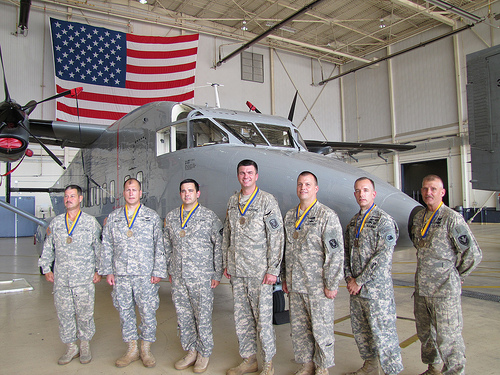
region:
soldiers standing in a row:
[20, 147, 490, 357]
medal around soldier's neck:
[58, 206, 83, 246]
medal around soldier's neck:
[116, 196, 150, 243]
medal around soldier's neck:
[168, 181, 206, 246]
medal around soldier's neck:
[231, 164, 256, 231]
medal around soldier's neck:
[288, 176, 320, 243]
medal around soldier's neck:
[341, 171, 376, 243]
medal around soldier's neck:
[411, 180, 448, 252]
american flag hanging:
[36, 17, 203, 114]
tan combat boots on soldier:
[43, 335, 93, 367]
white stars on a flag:
[51, 21, 119, 81]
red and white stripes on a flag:
[133, 35, 186, 107]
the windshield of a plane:
[143, 114, 303, 153]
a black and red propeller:
[0, 76, 63, 172]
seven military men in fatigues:
[47, 161, 498, 364]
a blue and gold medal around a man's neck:
[235, 196, 257, 223]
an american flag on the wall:
[41, 15, 198, 117]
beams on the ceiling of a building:
[227, 1, 488, 71]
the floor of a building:
[7, 275, 47, 345]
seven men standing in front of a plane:
[37, 77, 439, 277]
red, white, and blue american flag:
[43, 8, 218, 139]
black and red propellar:
[0, 45, 93, 203]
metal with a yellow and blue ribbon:
[61, 210, 86, 246]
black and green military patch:
[453, 228, 474, 251]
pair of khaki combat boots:
[110, 335, 165, 370]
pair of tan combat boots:
[50, 334, 98, 366]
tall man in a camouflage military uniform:
[218, 157, 285, 373]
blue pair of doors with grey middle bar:
[0, 193, 37, 243]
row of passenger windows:
[80, 177, 120, 208]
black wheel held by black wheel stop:
[270, 277, 295, 327]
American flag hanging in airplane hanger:
[35, 6, 217, 140]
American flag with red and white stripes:
[39, 6, 222, 133]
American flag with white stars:
[34, 8, 226, 127]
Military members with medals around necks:
[22, 165, 486, 366]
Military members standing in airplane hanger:
[27, 147, 476, 359]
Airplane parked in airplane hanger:
[34, 68, 466, 300]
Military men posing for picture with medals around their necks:
[23, 131, 483, 352]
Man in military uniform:
[25, 164, 116, 366]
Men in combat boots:
[25, 158, 170, 374]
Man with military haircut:
[392, 154, 486, 374]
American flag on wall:
[18, 30, 200, 127]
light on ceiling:
[236, 14, 257, 36]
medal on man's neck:
[57, 210, 85, 252]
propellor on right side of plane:
[0, 78, 84, 184]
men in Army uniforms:
[34, 157, 484, 374]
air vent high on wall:
[233, 50, 265, 84]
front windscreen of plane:
[165, 121, 279, 161]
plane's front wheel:
[275, 287, 288, 331]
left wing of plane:
[308, 134, 428, 161]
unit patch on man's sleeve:
[265, 209, 281, 236]